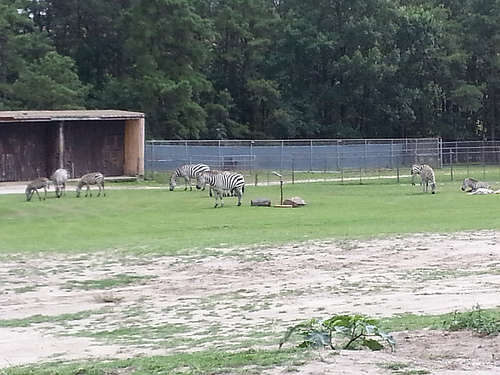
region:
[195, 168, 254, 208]
black and whtie zebra gazing in a pasture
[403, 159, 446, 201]
black and whtie zebra gazing in a pasture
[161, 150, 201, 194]
black and whtie zebra gazing in a pasture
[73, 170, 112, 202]
black and whtie zebra gazing in a pasture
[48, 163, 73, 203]
black and whtie zebra gazing in a pasture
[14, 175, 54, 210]
black and whtie zebra gazing in a pasture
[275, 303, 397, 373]
plant growing in center of pasture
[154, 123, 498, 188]
megtal security fencing around zebra exhibit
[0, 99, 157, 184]
wooden shelter in zebra exhibit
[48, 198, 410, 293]
grass in zebra exhibit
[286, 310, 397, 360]
plant sticking out of the ground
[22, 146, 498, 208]
zebra's grazing in a field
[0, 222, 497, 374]
dirt and grass on the ground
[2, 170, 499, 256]
grass field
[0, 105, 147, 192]
wooden shed by the zebra's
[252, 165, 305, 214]
rocks in the middle of the field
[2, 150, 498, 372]
a field with zebra's in it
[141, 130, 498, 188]
a metal fence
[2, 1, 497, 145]
green trees behind the fence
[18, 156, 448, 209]
zebra's grazing on the grass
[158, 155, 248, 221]
two zebras on a field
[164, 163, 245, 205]
zebras grazing on field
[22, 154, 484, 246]
large group of zebras on a field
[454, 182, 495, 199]
zebra laying down on field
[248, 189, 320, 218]
small rocks on a field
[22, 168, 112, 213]
three zebras grazing together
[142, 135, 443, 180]
long metal fence in background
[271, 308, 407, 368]
small plants growing from ground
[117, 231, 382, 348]
ground filled with grass and dirt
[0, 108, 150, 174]
wooden cover structure by fence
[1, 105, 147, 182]
wooden shed behind grass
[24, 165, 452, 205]
zebras eating the grass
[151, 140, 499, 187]
chain link fences behind grass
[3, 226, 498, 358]
dirt patches on grass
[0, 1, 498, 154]
tall green trees behind fences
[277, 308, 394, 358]
large green leaves on grass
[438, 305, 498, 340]
small green leaves on dirt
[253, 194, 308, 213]
two rocks in middle of grass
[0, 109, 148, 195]
wooden shed divided in middle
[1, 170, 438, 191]
dirt path next to grass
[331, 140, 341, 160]
part of a fence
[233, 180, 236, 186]
part of a zebra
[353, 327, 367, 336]
part of a plant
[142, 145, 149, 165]
edge of a wall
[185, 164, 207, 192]
head of a zebra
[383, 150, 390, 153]
edge of a fence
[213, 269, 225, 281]
edge of a lawn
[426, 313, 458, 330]
part of a field